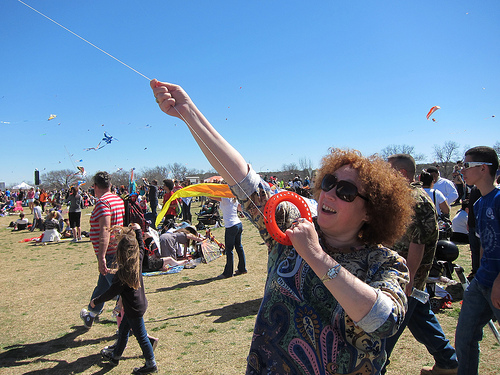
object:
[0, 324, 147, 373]
shadows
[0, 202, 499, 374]
ground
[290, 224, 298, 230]
ring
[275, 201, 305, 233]
hole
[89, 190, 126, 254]
shirt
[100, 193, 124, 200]
stripe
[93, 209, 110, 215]
stripe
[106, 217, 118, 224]
stripe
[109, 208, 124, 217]
stripe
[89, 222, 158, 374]
child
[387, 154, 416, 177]
hair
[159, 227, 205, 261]
woman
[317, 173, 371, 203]
sunglasses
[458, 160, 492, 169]
sunglasses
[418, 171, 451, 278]
womans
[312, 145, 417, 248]
hair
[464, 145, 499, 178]
hair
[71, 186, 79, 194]
hair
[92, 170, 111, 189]
hair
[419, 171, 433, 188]
hair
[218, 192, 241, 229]
shirt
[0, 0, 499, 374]
field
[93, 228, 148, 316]
shirt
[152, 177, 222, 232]
wooden bench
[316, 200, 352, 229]
smile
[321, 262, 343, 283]
watch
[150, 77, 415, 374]
kite flyer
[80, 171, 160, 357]
father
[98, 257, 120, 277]
holding hands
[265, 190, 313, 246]
kite reel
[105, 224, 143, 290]
hair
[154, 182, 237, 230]
kite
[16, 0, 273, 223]
kite string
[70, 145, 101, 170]
wind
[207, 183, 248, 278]
girl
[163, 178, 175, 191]
hair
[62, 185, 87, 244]
people